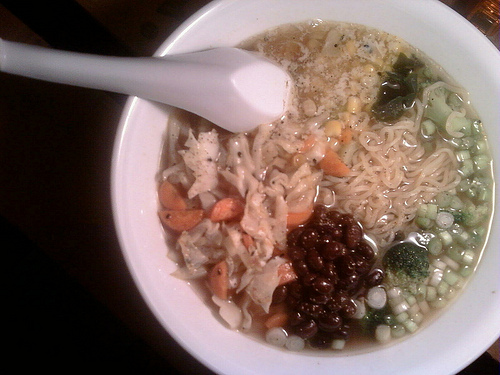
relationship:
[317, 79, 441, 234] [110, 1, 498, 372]
noodles are inside bowl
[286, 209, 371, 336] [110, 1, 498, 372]
beans in a bowl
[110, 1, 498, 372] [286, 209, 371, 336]
bowl has beans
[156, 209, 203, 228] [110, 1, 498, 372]
piece on bowl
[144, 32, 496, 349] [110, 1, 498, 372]
food on bowl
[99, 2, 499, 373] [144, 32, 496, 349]
white bowl of food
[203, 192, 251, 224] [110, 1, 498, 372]
food in bowl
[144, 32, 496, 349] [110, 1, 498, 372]
food in bowl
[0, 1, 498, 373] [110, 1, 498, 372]
table under bowl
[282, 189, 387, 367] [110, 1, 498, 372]
food on bowl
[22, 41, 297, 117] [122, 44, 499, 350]
white spoon in bowl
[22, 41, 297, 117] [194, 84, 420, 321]
white spoon in soup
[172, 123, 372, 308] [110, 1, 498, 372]
vegetables in bowl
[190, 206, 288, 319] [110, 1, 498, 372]
chicken in bowl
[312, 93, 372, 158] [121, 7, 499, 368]
kernels in soup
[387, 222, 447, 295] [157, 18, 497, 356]
broccoli in soup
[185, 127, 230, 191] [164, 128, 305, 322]
seasoning on chicken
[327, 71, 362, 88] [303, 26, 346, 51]
fat on top of broth